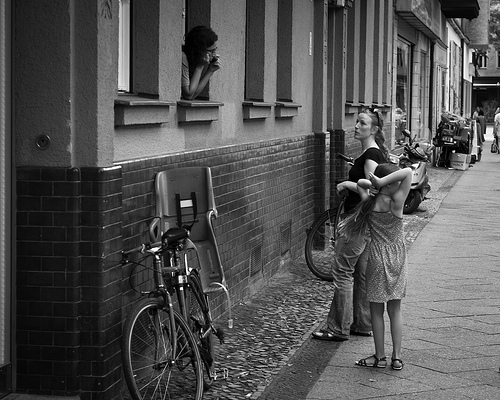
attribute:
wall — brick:
[225, 171, 283, 239]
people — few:
[468, 102, 498, 154]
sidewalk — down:
[291, 97, 498, 392]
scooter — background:
[390, 132, 434, 215]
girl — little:
[363, 151, 425, 198]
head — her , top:
[353, 92, 386, 148]